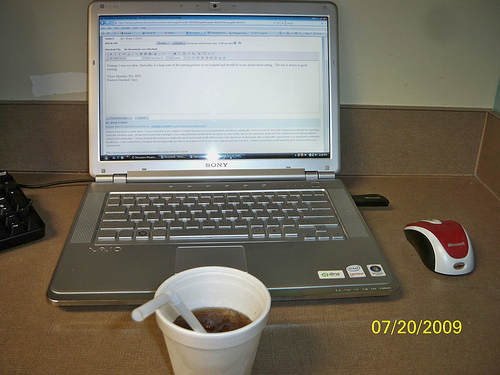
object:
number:
[370, 318, 463, 335]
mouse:
[402, 218, 476, 276]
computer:
[41, 3, 400, 307]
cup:
[152, 265, 272, 374]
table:
[0, 175, 500, 375]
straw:
[130, 289, 210, 335]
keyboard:
[0, 171, 46, 248]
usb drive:
[352, 193, 390, 206]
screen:
[99, 14, 332, 161]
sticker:
[317, 270, 346, 279]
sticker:
[346, 264, 367, 278]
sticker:
[367, 264, 387, 278]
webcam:
[209, 3, 220, 11]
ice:
[201, 307, 242, 330]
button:
[97, 230, 117, 240]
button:
[118, 229, 133, 240]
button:
[134, 229, 150, 240]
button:
[249, 226, 265, 238]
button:
[267, 226, 282, 237]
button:
[283, 227, 299, 238]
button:
[100, 222, 135, 229]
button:
[136, 221, 151, 229]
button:
[153, 221, 167, 230]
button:
[169, 220, 184, 229]